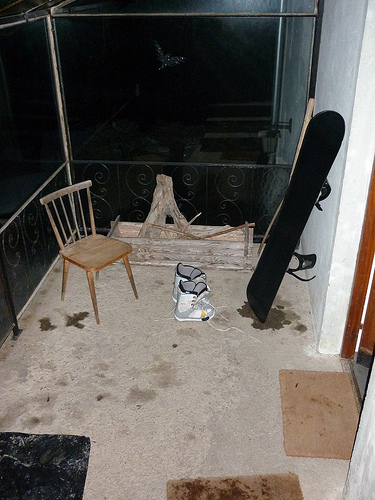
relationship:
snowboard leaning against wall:
[241, 95, 348, 331] [288, 0, 369, 357]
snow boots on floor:
[170, 262, 220, 332] [0, 240, 350, 498]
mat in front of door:
[278, 368, 363, 458] [338, 130, 373, 419]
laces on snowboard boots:
[196, 296, 262, 344] [169, 278, 217, 325]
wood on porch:
[103, 173, 251, 268] [0, 241, 319, 350]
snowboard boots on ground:
[169, 260, 247, 336] [296, 113, 340, 143]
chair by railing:
[20, 177, 152, 320] [0, 156, 291, 346]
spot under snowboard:
[234, 301, 288, 331] [244, 110, 344, 325]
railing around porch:
[1, 154, 295, 266] [0, 1, 364, 498]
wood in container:
[136, 170, 192, 240] [105, 216, 258, 273]